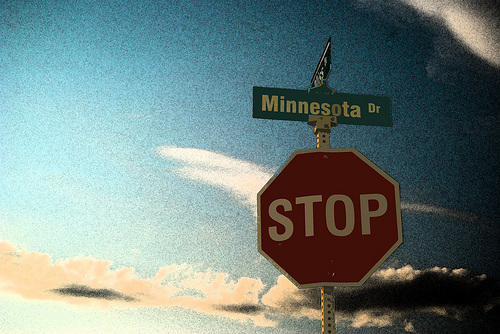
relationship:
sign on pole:
[262, 156, 412, 280] [315, 296, 341, 319]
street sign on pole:
[259, 80, 400, 149] [315, 296, 341, 319]